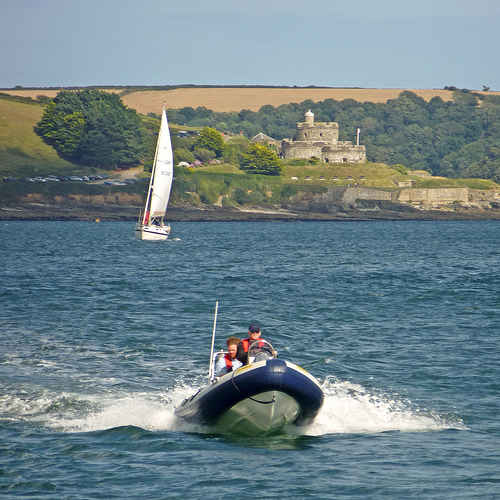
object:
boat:
[173, 299, 324, 438]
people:
[212, 316, 275, 377]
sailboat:
[135, 100, 177, 241]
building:
[281, 106, 367, 165]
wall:
[394, 185, 473, 211]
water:
[0, 220, 498, 318]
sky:
[0, 1, 498, 90]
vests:
[222, 347, 247, 363]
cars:
[68, 173, 90, 182]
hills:
[0, 100, 59, 186]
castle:
[254, 108, 368, 163]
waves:
[39, 373, 166, 432]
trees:
[146, 87, 500, 179]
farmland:
[118, 88, 453, 115]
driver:
[238, 318, 274, 366]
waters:
[1, 252, 500, 373]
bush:
[32, 88, 143, 171]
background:
[0, 84, 500, 221]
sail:
[142, 99, 175, 228]